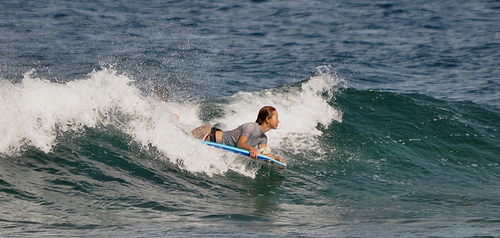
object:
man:
[173, 105, 288, 169]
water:
[0, 2, 498, 235]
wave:
[0, 59, 349, 190]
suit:
[187, 122, 269, 150]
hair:
[255, 105, 275, 125]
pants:
[190, 124, 222, 143]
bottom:
[190, 124, 222, 145]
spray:
[0, 39, 160, 165]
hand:
[237, 124, 259, 159]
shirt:
[222, 122, 268, 148]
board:
[195, 139, 289, 169]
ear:
[264, 117, 271, 123]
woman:
[190, 103, 280, 160]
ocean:
[0, 0, 500, 237]